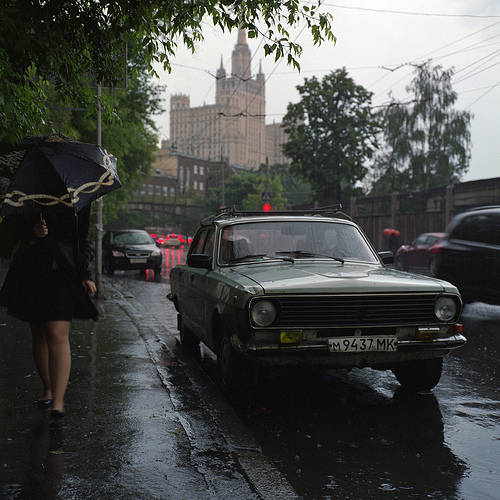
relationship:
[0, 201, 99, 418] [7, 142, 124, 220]
lady holding umbrella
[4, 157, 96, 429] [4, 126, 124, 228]
lady holding umbrella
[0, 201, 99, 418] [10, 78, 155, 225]
lady carrying umbrella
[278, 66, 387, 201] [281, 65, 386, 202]
leaves on tree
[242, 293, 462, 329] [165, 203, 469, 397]
headlights on car